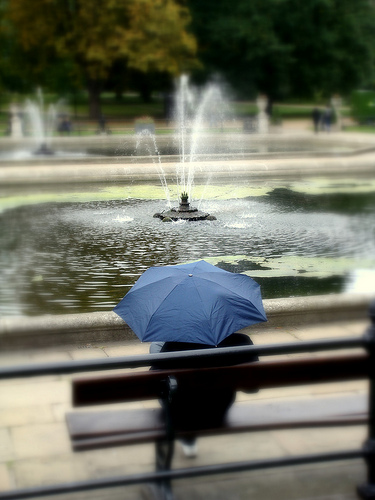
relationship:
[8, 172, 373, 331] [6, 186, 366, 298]
ripples on water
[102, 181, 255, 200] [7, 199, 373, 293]
scum on pond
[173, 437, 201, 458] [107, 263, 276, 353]
shoes under umbrella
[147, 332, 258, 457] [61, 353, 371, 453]
person sitting on bench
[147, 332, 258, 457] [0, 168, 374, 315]
person sitting in front of fountain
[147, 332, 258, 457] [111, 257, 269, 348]
person holding umberella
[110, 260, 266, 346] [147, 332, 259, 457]
umbrella over man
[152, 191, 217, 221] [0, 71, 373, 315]
fountain spraying water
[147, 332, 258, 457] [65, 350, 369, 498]
person sitting on a bench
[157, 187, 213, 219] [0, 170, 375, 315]
black fountain in water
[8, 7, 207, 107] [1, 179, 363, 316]
tree past water